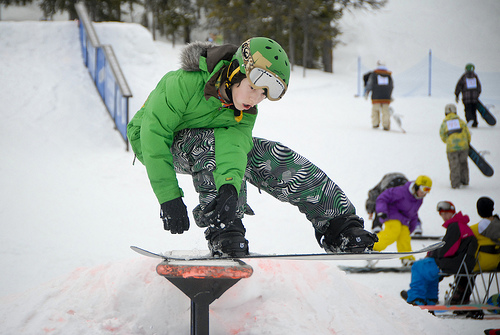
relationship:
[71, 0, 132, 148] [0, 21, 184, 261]
ramp on hill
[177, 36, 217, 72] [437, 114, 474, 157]
fur on jacket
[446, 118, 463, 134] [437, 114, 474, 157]
bib number on jacket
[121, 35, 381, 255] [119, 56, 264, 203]
snowboarder wearing jacket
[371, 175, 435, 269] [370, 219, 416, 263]
snowboarder wearing snowpants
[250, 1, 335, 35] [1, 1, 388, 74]
leaves on trees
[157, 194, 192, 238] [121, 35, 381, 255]
right black glove of snowboarder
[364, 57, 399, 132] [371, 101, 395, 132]
snowboarder wearing snowpants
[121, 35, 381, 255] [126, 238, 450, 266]
snowboarder on snowboard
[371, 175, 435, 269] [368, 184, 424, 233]
snowboarder wearing jacket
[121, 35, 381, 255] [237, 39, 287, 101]
snowboarder with goggles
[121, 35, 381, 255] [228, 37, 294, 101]
snowboarder wearing helmet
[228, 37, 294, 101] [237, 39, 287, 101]
helmet with goggles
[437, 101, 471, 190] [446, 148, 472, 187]
snowboarder wearing snowpants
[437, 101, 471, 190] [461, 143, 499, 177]
snowboarder carrying snowboard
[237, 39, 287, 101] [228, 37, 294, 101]
goggles on helmet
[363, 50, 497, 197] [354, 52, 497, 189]
snowboarders climbing hill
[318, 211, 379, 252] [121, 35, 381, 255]
left foot of snowboarder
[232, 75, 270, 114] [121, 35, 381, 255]
face of snowboarder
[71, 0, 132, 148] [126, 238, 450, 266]
ramp for snowboard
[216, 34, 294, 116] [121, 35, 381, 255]
head of snowboarder